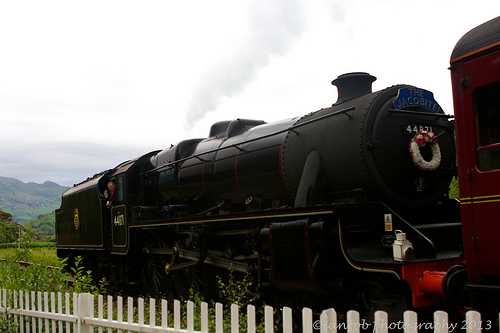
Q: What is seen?
A: Train.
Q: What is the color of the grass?
A: Green.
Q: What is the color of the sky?
A: White.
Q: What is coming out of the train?
A: Smoke.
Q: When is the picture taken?
A: Daytime.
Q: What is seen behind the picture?
A: Mountain.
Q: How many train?
A: 1.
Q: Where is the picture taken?
A: In Scotland.